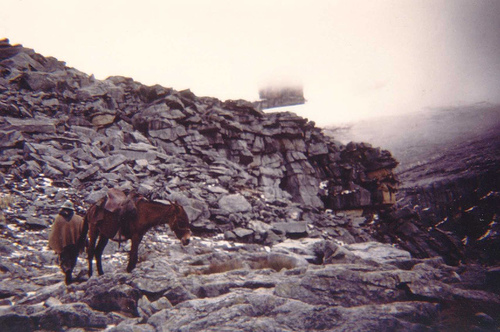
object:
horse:
[80, 185, 191, 277]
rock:
[266, 241, 310, 268]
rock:
[264, 199, 296, 216]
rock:
[328, 180, 371, 210]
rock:
[73, 88, 260, 186]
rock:
[150, 285, 340, 332]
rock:
[289, 175, 325, 210]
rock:
[250, 249, 303, 269]